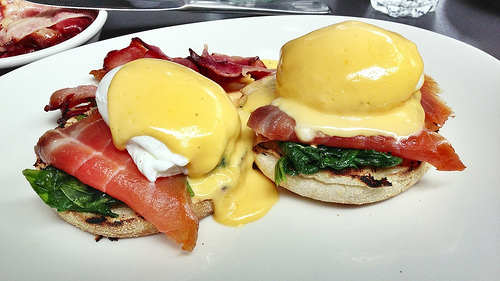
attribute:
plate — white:
[25, 15, 490, 281]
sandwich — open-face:
[62, 29, 413, 239]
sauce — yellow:
[123, 27, 416, 187]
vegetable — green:
[37, 155, 148, 229]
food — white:
[94, 39, 198, 202]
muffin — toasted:
[35, 202, 224, 244]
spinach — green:
[34, 143, 115, 218]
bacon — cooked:
[116, 33, 283, 90]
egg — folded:
[99, 81, 176, 156]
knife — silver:
[58, 1, 324, 17]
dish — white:
[1, 14, 112, 63]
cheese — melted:
[129, 84, 320, 234]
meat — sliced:
[64, 84, 220, 232]